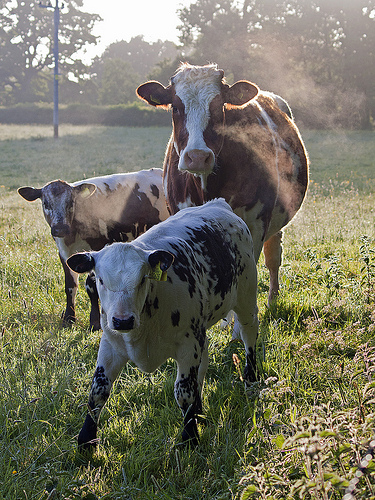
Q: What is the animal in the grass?
A: Cows.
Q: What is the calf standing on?
A: Grass.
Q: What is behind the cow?
A: A calf.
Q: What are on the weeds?
A: Flowers.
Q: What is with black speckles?
A: A white cow.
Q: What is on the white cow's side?
A: Black speckles.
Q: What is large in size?
A: A cow.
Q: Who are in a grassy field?
A: Cows.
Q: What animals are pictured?
A: Cows.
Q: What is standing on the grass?
A: Cows.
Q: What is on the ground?
A: Grass.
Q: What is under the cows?
A: Grass.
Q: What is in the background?
A: Trees.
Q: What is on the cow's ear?
A: A tag.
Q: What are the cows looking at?
A: The camera.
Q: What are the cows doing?
A: Looking at the camera.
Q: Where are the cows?
A: A field.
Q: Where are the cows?
A: In a field.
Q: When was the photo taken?
A: Daytime.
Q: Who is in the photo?
A: Nobody.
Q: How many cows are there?
A: Three.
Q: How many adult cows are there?
A: One.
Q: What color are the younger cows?
A: White and black.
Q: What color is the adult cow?
A: Brown and white.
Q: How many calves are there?
A: Two.